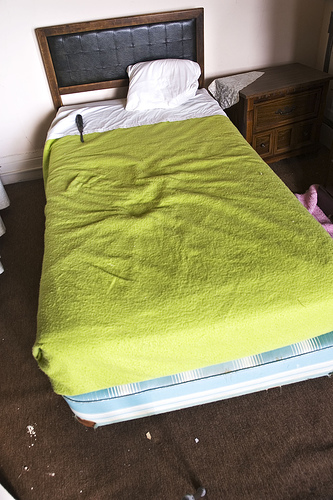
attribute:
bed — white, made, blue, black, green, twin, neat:
[24, 98, 328, 418]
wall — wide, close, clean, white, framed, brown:
[2, 3, 325, 169]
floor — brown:
[144, 452, 211, 485]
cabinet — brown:
[212, 57, 322, 163]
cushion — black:
[45, 15, 198, 89]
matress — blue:
[26, 263, 322, 407]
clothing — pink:
[289, 178, 322, 241]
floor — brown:
[2, 164, 319, 498]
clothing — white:
[207, 62, 268, 120]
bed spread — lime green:
[35, 99, 322, 395]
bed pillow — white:
[121, 53, 203, 112]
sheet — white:
[40, 81, 232, 137]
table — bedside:
[211, 56, 321, 164]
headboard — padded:
[30, 3, 205, 111]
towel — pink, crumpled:
[292, 181, 322, 220]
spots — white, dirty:
[8, 409, 212, 497]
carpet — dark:
[0, 0, 322, 497]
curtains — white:
[0, 172, 12, 281]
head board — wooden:
[32, 4, 206, 114]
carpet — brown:
[1, 177, 319, 498]